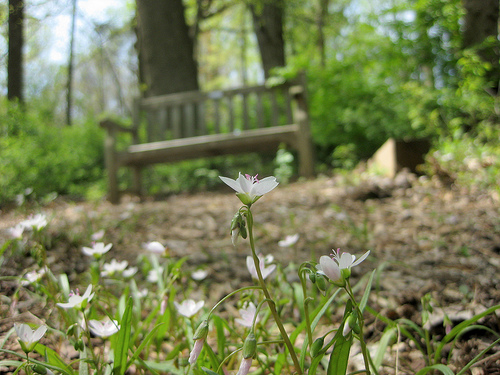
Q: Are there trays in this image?
A: No, there are no trays.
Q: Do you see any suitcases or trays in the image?
A: No, there are no trays or suitcases.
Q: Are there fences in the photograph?
A: No, there are no fences.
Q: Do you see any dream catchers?
A: No, there are no dream catchers.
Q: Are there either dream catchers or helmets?
A: No, there are no dream catchers or helmets.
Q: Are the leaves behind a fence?
A: No, the leaves are behind a bench.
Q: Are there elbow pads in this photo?
A: No, there are no elbow pads.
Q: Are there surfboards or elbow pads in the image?
A: No, there are no elbow pads or surfboards.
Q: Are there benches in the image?
A: Yes, there is a bench.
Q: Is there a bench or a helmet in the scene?
A: Yes, there is a bench.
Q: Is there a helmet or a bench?
A: Yes, there is a bench.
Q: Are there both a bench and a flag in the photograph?
A: No, there is a bench but no flags.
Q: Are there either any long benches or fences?
A: Yes, there is a long bench.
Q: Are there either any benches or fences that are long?
A: Yes, the bench is long.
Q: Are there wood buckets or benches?
A: Yes, there is a wood bench.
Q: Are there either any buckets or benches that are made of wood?
A: Yes, the bench is made of wood.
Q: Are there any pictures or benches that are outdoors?
A: Yes, the bench is outdoors.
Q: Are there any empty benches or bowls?
A: Yes, there is an empty bench.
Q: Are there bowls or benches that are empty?
A: Yes, the bench is empty.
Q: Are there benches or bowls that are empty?
A: Yes, the bench is empty.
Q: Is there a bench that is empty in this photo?
A: Yes, there is an empty bench.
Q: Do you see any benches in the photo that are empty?
A: Yes, there is a bench that is empty.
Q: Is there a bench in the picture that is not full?
A: Yes, there is a empty bench.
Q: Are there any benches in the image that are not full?
A: Yes, there is a empty bench.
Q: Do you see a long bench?
A: Yes, there is a long bench.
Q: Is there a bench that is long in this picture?
A: Yes, there is a long bench.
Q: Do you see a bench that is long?
A: Yes, there is a bench that is long.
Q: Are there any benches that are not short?
A: Yes, there is a long bench.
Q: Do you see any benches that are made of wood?
A: Yes, there is a bench that is made of wood.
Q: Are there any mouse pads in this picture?
A: No, there are no mouse pads.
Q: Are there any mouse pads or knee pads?
A: No, there are no mouse pads or knee pads.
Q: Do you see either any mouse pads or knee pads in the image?
A: No, there are no mouse pads or knee pads.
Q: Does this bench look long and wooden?
A: Yes, the bench is long and wooden.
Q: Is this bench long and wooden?
A: Yes, the bench is long and wooden.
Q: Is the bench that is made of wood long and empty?
A: Yes, the bench is long and empty.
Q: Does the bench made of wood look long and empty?
A: Yes, the bench is long and empty.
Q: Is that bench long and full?
A: No, the bench is long but empty.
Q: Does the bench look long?
A: Yes, the bench is long.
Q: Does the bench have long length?
A: Yes, the bench is long.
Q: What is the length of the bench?
A: The bench is long.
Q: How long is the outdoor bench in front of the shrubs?
A: The bench is long.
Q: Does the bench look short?
A: No, the bench is long.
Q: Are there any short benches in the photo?
A: No, there is a bench but it is long.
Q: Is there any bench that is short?
A: No, there is a bench but it is long.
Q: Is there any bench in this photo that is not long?
A: No, there is a bench but it is long.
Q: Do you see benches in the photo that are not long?
A: No, there is a bench but it is long.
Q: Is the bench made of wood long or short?
A: The bench is long.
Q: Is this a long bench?
A: Yes, this is a long bench.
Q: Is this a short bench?
A: No, this is a long bench.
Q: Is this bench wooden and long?
A: Yes, the bench is wooden and long.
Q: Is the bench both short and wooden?
A: No, the bench is wooden but long.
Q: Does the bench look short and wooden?
A: No, the bench is wooden but long.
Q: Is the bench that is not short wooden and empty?
A: Yes, the bench is wooden and empty.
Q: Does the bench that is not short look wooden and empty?
A: Yes, the bench is wooden and empty.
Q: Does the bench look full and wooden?
A: No, the bench is wooden but empty.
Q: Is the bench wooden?
A: Yes, the bench is wooden.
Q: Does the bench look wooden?
A: Yes, the bench is wooden.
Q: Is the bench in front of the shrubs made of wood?
A: Yes, the bench is made of wood.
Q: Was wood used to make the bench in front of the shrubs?
A: Yes, the bench is made of wood.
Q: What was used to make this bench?
A: The bench is made of wood.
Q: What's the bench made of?
A: The bench is made of wood.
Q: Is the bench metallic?
A: No, the bench is wooden.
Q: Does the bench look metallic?
A: No, the bench is wooden.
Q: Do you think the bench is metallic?
A: No, the bench is wooden.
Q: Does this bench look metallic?
A: No, the bench is wooden.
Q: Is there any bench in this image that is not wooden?
A: No, there is a bench but it is wooden.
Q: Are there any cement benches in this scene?
A: No, there is a bench but it is made of wood.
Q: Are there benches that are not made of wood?
A: No, there is a bench but it is made of wood.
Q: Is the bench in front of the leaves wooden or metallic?
A: The bench is wooden.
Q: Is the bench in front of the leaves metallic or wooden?
A: The bench is wooden.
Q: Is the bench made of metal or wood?
A: The bench is made of wood.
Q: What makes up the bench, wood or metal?
A: The bench is made of wood.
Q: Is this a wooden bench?
A: Yes, this is a wooden bench.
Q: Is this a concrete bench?
A: No, this is a wooden bench.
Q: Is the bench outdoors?
A: Yes, the bench is outdoors.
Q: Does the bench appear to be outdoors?
A: Yes, the bench is outdoors.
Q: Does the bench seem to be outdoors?
A: Yes, the bench is outdoors.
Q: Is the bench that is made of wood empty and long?
A: Yes, the bench is empty and long.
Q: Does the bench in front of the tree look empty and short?
A: No, the bench is empty but long.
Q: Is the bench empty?
A: Yes, the bench is empty.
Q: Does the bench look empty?
A: Yes, the bench is empty.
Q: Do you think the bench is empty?
A: Yes, the bench is empty.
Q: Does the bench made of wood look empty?
A: Yes, the bench is empty.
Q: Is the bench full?
A: No, the bench is empty.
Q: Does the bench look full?
A: No, the bench is empty.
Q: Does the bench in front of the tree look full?
A: No, the bench is empty.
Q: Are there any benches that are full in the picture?
A: No, there is a bench but it is empty.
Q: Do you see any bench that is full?
A: No, there is a bench but it is empty.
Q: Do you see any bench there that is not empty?
A: No, there is a bench but it is empty.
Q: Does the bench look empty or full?
A: The bench is empty.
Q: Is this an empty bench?
A: Yes, this is an empty bench.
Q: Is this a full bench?
A: No, this is an empty bench.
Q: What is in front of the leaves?
A: The bench is in front of the leaves.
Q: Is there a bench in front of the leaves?
A: Yes, there is a bench in front of the leaves.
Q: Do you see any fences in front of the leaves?
A: No, there is a bench in front of the leaves.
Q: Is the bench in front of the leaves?
A: Yes, the bench is in front of the leaves.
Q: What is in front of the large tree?
A: The bench is in front of the tree.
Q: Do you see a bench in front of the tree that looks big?
A: Yes, there is a bench in front of the tree.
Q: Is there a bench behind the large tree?
A: No, the bench is in front of the tree.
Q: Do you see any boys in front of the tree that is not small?
A: No, there is a bench in front of the tree.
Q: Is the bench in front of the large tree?
A: Yes, the bench is in front of the tree.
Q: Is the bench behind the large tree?
A: No, the bench is in front of the tree.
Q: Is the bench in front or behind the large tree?
A: The bench is in front of the tree.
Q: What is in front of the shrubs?
A: The bench is in front of the shrubs.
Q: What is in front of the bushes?
A: The bench is in front of the shrubs.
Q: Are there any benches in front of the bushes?
A: Yes, there is a bench in front of the bushes.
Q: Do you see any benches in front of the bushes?
A: Yes, there is a bench in front of the bushes.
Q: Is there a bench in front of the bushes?
A: Yes, there is a bench in front of the bushes.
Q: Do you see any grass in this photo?
A: Yes, there is grass.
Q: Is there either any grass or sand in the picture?
A: Yes, there is grass.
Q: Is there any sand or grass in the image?
A: Yes, there is grass.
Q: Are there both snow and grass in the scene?
A: No, there is grass but no snow.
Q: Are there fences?
A: No, there are no fences.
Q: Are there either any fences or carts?
A: No, there are no fences or carts.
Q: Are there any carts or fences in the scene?
A: No, there are no fences or carts.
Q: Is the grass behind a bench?
A: Yes, the grass is behind a bench.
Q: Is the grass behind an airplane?
A: No, the grass is behind a bench.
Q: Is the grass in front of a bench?
A: No, the grass is behind a bench.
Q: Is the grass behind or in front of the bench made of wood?
A: The grass is behind the bench.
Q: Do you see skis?
A: No, there are no skis.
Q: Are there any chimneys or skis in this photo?
A: No, there are no skis or chimneys.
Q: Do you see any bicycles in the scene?
A: No, there are no bicycles.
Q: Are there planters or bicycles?
A: No, there are no bicycles or planters.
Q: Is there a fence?
A: No, there are no fences.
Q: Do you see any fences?
A: No, there are no fences.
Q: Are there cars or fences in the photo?
A: No, there are no fences or cars.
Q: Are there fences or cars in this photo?
A: No, there are no fences or cars.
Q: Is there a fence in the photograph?
A: No, there are no fences.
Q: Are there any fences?
A: No, there are no fences.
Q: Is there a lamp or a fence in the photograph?
A: No, there are no fences or lamps.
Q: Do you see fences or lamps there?
A: No, there are no fences or lamps.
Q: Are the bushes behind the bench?
A: Yes, the bushes are behind the bench.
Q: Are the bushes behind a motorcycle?
A: No, the bushes are behind the bench.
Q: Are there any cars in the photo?
A: No, there are no cars.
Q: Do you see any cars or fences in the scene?
A: No, there are no cars or fences.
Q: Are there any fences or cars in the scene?
A: No, there are no cars or fences.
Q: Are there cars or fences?
A: No, there are no cars or fences.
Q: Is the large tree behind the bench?
A: Yes, the tree is behind the bench.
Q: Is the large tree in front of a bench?
A: No, the tree is behind a bench.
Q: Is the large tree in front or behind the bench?
A: The tree is behind the bench.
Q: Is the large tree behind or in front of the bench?
A: The tree is behind the bench.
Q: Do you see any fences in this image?
A: No, there are no fences.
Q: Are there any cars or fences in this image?
A: No, there are no fences or cars.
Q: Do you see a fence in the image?
A: No, there are no fences.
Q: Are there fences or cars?
A: No, there are no fences or cars.